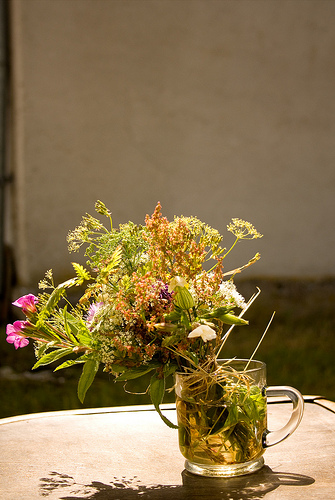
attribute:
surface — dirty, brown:
[2, 396, 333, 496]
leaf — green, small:
[218, 309, 251, 327]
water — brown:
[171, 408, 285, 462]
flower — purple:
[157, 285, 174, 302]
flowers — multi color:
[7, 197, 259, 429]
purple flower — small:
[82, 299, 104, 328]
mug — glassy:
[148, 330, 315, 480]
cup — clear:
[171, 355, 306, 476]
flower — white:
[218, 282, 227, 291]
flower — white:
[185, 324, 216, 343]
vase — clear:
[173, 356, 304, 478]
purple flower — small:
[12, 287, 79, 370]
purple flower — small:
[5, 318, 32, 348]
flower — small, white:
[188, 323, 217, 342]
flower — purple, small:
[6, 286, 58, 320]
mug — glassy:
[174, 354, 309, 485]